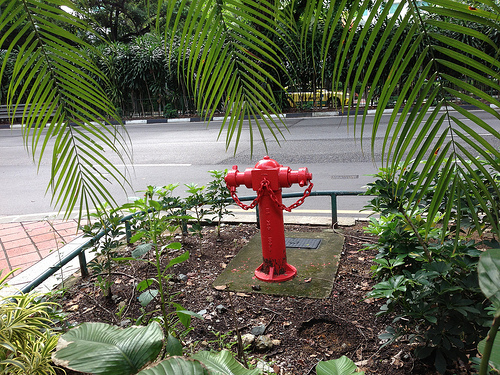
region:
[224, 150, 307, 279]
this is a hydrant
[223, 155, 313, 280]
the hydrant is red in color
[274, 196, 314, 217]
this is a chain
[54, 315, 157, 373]
this is the leaf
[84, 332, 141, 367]
the leaf is green inn color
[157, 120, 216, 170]
this is the road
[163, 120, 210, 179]
the road is tarmacked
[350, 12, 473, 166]
these are the leaves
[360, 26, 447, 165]
the leaves are thin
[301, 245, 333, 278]
this is the floor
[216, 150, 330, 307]
hydrant on the sidewalk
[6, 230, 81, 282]
sidewalk of brick blocks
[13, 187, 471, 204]
rail around the plant area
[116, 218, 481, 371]
plants in enclosed area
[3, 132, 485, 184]
road for vehicles to travel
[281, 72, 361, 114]
vehicle on the lot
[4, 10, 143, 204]
branch on a tree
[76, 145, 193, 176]
strips on the road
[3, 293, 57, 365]
plant in enclosed area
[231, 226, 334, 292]
concrete block hydrant rests on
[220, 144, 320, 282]
the hydrant is red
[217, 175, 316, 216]
chain on the back of the hydrant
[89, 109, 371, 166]
the street is empty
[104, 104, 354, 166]
the street is grey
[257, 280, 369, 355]
the dirt is brown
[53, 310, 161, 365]
the leaf is wide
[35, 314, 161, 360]
the leaf has lines on it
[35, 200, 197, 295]
the rail is surrounding the greenery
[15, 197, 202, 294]
the rail is green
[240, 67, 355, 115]
a car in the backgrouns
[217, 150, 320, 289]
A red water hydrant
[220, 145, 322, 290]
A red water hydrant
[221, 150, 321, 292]
A red water hydrant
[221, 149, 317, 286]
A red water hydrant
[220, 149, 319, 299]
A red water hydrant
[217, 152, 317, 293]
A red water hydrant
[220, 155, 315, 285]
The red fire hydrant.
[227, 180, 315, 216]
The chain on the fire hydrant.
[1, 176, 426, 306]
The green bar surrounding the garden area.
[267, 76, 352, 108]
The yellow car in the parking lot.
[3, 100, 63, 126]
The bench on the left.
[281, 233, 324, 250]
The water cap in front of the fire hydrant.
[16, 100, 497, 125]
The black and white curb.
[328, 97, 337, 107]
The front tire of the yellow car.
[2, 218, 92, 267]
The brick sidewalk.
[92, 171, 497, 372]
The plants in the garden area.